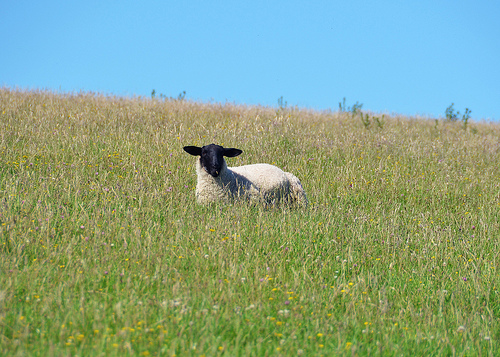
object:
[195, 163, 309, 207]
fur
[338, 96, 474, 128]
shrubbery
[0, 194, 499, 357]
flower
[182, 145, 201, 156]
ear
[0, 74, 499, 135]
crest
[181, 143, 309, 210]
goat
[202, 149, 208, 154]
right eye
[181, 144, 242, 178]
black head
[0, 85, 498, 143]
weeds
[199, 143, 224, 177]
black face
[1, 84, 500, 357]
field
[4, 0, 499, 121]
sky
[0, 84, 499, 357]
grass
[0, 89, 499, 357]
hill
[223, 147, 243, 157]
ear